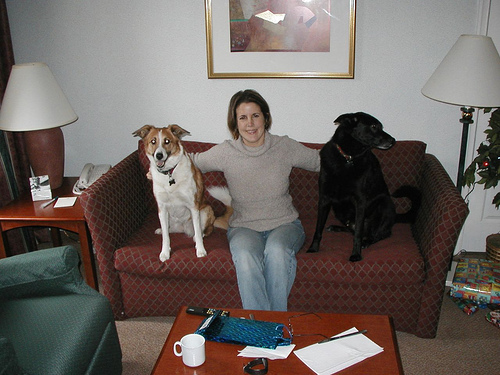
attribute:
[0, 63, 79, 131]
lamp shade — white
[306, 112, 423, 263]
dog — black, brown, looking to the right, sitting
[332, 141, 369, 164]
collar — brown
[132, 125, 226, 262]
dog — white, facing forward, tan, brown, sitting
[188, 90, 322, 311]
woman — smiling, sitting, young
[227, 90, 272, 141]
hair — brown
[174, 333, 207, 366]
coffee mug — white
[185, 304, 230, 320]
remote control — black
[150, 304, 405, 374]
table — brown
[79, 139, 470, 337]
couch — maroon, burgundy, red, for sitting, gold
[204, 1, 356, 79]
picture — framed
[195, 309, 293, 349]
gift bag — blue, empty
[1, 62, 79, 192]
lamp — small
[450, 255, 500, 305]
gift — stacked, wrapped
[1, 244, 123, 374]
recliner — green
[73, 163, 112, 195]
telephone — white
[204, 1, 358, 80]
frame — gold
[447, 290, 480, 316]
gift — stacked, wrapped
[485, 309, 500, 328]
gift — stacked, wrapped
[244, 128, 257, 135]
smile — big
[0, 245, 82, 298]
arm — blue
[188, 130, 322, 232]
sweater — tan